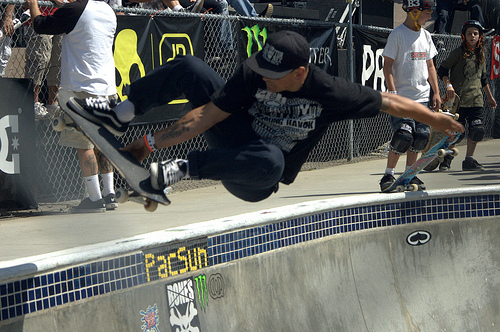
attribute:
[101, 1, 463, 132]
advertisements — event advertisements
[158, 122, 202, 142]
tattoo — dark colored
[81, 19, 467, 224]
man — skateboarding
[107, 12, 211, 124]
signs — sponsor signs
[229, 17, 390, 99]
signs — sponsor signs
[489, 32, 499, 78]
signs — sponsor signs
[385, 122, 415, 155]
black kneepad — a pair, black 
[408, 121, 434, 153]
black kneepad — a pair, black 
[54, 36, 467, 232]
man — doing a trick 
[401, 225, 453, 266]
spade — black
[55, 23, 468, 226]
guy — stunt skating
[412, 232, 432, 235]
background — white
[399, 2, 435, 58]
straps — yellow